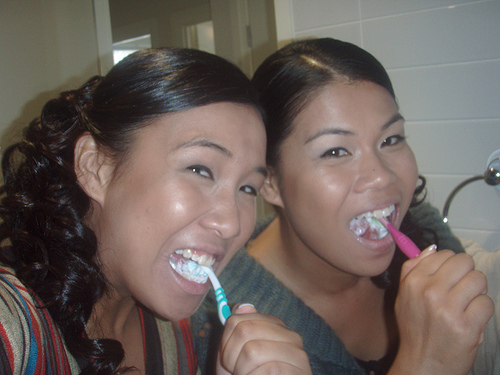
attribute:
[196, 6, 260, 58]
door — open, white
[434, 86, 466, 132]
wall — white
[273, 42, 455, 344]
girl — brushing, smiling, indoors, looking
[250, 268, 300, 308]
sweater — grey, gray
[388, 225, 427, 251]
brush — orange, pink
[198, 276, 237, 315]
tooth brush — green, blue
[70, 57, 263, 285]
friend — brushing